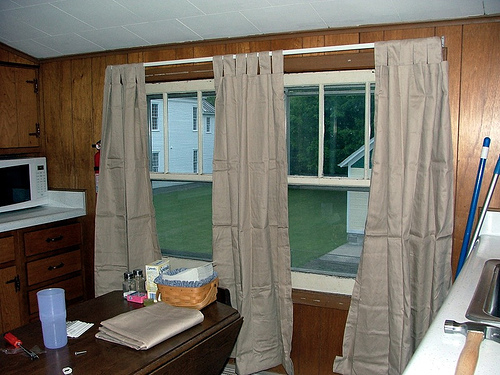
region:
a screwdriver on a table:
[5, 324, 39, 362]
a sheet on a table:
[95, 292, 208, 353]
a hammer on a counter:
[438, 315, 498, 374]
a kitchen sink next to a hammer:
[461, 252, 498, 324]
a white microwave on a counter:
[0, 152, 60, 220]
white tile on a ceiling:
[0, 0, 499, 70]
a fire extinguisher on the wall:
[88, 141, 108, 205]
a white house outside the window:
[140, 97, 230, 193]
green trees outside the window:
[284, 87, 379, 195]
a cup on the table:
[33, 285, 71, 350]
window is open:
[146, 88, 221, 274]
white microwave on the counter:
[0, 155, 57, 212]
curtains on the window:
[91, 34, 457, 373]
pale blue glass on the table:
[34, 285, 71, 350]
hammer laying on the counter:
[440, 314, 498, 374]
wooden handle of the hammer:
[450, 331, 482, 373]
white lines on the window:
[286, 85, 375, 177]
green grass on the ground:
[142, 177, 360, 266]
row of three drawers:
[21, 219, 88, 304]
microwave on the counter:
[1, 154, 58, 214]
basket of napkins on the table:
[153, 270, 223, 305]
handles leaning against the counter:
[459, 133, 491, 264]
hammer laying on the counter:
[438, 315, 487, 372]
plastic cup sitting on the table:
[33, 286, 67, 356]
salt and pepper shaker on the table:
[123, 261, 140, 291]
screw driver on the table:
[5, 325, 37, 363]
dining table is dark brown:
[18, 231, 249, 373]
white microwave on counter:
[0, 133, 75, 241]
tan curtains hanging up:
[65, 17, 477, 371]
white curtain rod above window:
[78, 28, 442, 88]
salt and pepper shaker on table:
[110, 250, 152, 302]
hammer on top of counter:
[410, 272, 497, 370]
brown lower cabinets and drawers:
[0, 189, 95, 325]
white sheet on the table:
[95, 288, 204, 357]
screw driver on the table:
[1, 321, 41, 366]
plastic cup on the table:
[33, 285, 74, 352]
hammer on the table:
[441, 315, 498, 369]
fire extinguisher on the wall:
[84, 137, 110, 217]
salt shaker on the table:
[119, 267, 144, 299]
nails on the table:
[68, 348, 94, 359]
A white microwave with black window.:
[0, 158, 48, 214]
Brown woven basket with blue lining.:
[153, 269, 219, 312]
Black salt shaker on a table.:
[132, 269, 145, 295]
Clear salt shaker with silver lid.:
[121, 270, 136, 293]